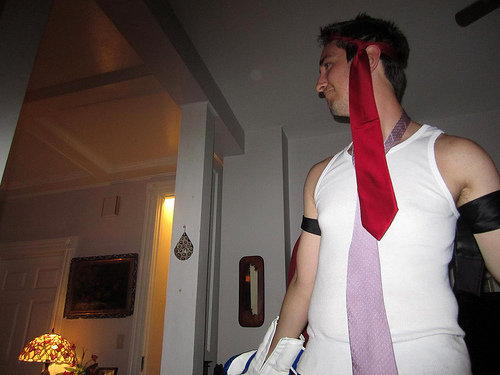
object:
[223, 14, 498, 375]
man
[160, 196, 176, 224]
light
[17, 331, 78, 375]
lamp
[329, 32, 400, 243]
tie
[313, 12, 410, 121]
head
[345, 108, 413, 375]
necktie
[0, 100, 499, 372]
wall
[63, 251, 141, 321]
painting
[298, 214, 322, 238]
armband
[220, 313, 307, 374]
glove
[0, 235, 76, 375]
door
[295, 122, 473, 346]
shirt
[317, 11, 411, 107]
hair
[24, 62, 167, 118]
trim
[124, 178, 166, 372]
edge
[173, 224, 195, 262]
hanging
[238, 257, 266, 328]
object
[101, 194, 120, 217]
square